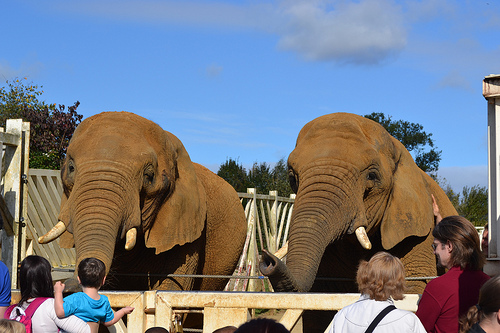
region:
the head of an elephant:
[50, 108, 176, 260]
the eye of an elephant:
[139, 163, 158, 184]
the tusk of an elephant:
[119, 223, 141, 254]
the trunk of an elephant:
[253, 181, 345, 294]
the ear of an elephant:
[138, 134, 217, 258]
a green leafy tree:
[0, 71, 90, 172]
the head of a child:
[73, 253, 110, 296]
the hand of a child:
[50, 276, 68, 295]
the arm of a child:
[48, 289, 80, 320]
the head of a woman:
[427, 208, 487, 270]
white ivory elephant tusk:
[34, 220, 70, 248]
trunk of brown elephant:
[256, 185, 355, 294]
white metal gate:
[35, 285, 421, 330]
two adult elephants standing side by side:
[33, 108, 466, 330]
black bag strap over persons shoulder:
[333, 303, 427, 330]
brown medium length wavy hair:
[353, 250, 409, 302]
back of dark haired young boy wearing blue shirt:
[52, 257, 134, 326]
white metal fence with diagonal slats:
[0, 114, 487, 331]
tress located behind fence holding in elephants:
[1, 73, 441, 285]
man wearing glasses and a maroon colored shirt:
[416, 214, 487, 330]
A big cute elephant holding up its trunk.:
[253, 88, 416, 278]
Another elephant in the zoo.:
[45, 89, 240, 283]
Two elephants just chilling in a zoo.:
[22, 82, 409, 294]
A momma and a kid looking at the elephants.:
[13, 247, 140, 330]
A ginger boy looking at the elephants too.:
[323, 250, 427, 331]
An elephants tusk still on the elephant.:
[347, 225, 376, 251]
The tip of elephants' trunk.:
[250, 245, 327, 293]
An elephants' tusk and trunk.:
[29, 212, 149, 251]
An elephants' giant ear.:
[145, 142, 214, 258]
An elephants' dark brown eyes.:
[60, 152, 162, 190]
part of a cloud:
[323, 4, 395, 62]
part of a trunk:
[283, 207, 314, 262]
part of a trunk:
[284, 182, 315, 244]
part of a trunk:
[281, 224, 316, 273]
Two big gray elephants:
[35, 110, 463, 292]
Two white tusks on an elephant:
[33, 215, 143, 255]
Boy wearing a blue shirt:
[52, 255, 135, 328]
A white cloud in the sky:
[274, 2, 414, 73]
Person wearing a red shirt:
[416, 215, 491, 331]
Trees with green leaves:
[1, 78, 488, 229]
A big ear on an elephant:
[379, 141, 437, 250]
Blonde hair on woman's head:
[354, 248, 410, 304]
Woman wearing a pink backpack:
[2, 253, 63, 331]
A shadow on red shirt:
[458, 262, 491, 313]